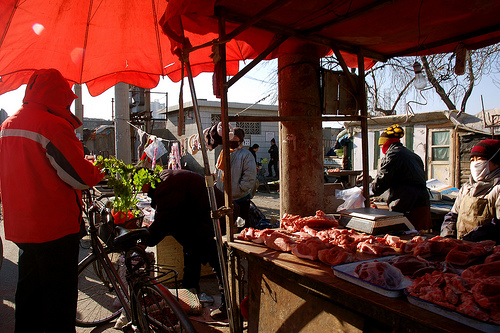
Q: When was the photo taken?
A: Daytime.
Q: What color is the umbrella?
A: Orange.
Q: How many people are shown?
A: Seven.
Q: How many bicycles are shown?
A: One.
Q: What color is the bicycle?
A: Red.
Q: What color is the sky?
A: Blue.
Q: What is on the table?
A: Meat.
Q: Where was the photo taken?
A: In the markets.